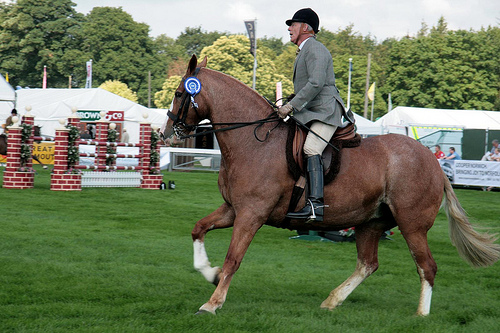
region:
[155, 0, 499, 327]
a rider on a horse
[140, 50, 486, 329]
body of horse is brown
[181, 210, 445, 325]
legs of horse are white and brown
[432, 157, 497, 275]
tail of horse is long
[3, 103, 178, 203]
obstacles for horse race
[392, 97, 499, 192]
people in a tent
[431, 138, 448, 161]
person with red top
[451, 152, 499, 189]
a banner in front a table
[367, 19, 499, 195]
green trees behind a tent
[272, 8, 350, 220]
Man riding on horse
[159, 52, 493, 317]
Brown horse with man on top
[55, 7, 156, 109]
Tree is next to tree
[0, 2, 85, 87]
Tree is next to tree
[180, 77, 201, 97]
Blue tag on horse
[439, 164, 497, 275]
Blonde tail on horse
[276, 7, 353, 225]
Man wearing riding cap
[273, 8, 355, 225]
Man wearing gray jacket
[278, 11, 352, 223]
Man wearing long black riding boots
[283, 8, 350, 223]
Man wearing khaki riding pants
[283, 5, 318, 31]
Male horse rider black helmet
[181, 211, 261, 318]
Dancing brown and white horse legs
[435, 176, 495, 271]
Brown and beige horse tail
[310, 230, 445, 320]
Two standing horse legs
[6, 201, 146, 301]
Grass covering the ground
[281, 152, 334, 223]
Male horse rider black boots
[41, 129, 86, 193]
Red and white brick like structure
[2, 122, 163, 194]
Four red and white columns standing on the ground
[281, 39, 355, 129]
Male horse rider's jacket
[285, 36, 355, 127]
Dark grey horse rider's jacket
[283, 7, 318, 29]
Black riding helmet on a man.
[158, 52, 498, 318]
A brown horse with some white on it.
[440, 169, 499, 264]
A groomed horses tail.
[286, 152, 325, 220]
The black shiny left boot of a rider.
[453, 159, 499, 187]
A white banner with writing on it behind a horse.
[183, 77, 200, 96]
A blue and white circle on the horses head.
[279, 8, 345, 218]
A mature grey haired man on a horse in a grey coat.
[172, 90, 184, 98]
The left dark eye of a horse.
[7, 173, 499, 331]
Green grass on the ground.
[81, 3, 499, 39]
A blue and white sky.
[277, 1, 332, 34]
man has black cap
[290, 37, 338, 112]
man has grey coat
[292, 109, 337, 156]
man has tan pants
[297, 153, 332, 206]
man has dark green boots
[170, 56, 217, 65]
horse has brown ears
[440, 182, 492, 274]
horse has light brown tail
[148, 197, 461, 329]
brown and white legs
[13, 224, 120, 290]
grass is green and thick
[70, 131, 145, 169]
red and white rails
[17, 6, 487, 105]
thick green trees in distance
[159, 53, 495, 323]
a dressage horse in competition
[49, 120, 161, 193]
a jump on the course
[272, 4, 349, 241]
a man riding on a dressage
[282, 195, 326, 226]
the left stirrup on the horse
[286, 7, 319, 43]
a hat on the rider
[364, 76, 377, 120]
a flag in the distance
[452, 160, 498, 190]
a sign by the fence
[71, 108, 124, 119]
a sign on a tent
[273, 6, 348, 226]
man wearing gray jacket riding a horse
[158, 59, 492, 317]
brown and white horse on horse show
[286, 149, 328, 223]
black left boot of man